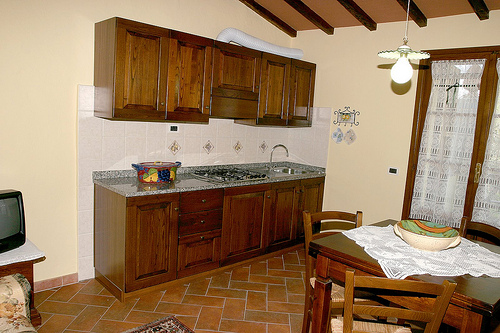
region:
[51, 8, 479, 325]
Picture of a kitchen.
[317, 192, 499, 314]
Square wooden kitchen table.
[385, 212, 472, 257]
Large round bowl on table.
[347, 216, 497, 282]
Small white lace table covering.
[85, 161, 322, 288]
Bottom kitchen cabinets made of wood.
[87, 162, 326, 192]
Marble countertop on lower cabinet.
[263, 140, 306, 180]
Silver faucet on sink.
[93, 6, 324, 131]
Top cabinets made of wood.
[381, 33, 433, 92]
Light fixture hanging from ceiling.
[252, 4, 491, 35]
Exposed wooden rafters in ceiling.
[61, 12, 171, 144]
a wooden cabinet door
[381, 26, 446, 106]
an overhead light fixture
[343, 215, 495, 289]
a white cloth on the table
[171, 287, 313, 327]
a floor made of brick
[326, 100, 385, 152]
decorative items on the wall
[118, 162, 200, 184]
a pot with fruit designs on it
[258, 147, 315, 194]
a kitchen sink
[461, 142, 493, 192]
a brass plated door knob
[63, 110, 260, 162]
a tile backsplash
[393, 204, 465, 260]
bowl on top of table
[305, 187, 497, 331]
bowl on top of table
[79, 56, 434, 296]
small neat kitchen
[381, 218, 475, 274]
colorful bowl on table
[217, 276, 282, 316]
red brick style tile on kitchen floor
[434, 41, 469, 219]
curtains on glass door front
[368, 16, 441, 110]
round light hanging over large table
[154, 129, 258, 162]
kitchen back splash with decorative tiles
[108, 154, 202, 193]
colorful pot with two handles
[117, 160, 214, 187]
cook pot with fruit decorations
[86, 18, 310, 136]
upper kitchen cabinets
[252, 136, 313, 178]
small kitchen sink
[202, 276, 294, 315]
the floor is brown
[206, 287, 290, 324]
the floor has tiles on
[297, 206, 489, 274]
the table clothe is white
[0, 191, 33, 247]
the small tv is off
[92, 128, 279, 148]
the tiles are white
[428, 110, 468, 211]
the curtain is white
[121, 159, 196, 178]
the pot is decorated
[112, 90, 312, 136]
the cabinet is brown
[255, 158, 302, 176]
the surface is concrete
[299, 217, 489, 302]
table and chairs are wooden